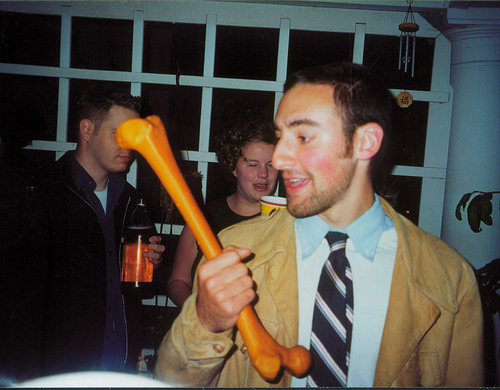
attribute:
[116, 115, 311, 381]
bone — large, orange, femur, long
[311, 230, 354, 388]
neck tie — black, blue, striped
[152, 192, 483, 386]
jacket — leather, tan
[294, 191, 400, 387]
shirt — light blue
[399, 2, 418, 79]
windchimes — small, wood, metal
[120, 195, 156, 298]
bottle — large, 40 oz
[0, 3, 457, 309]
wall — white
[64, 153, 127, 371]
shirt — purple, button down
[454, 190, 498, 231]
branch — limp, green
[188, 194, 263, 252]
shirt — sleeveless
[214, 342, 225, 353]
button — brown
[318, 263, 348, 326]
stripe — navy blue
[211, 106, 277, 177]
hair — curly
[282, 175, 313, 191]
mouth — open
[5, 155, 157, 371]
jacket — black